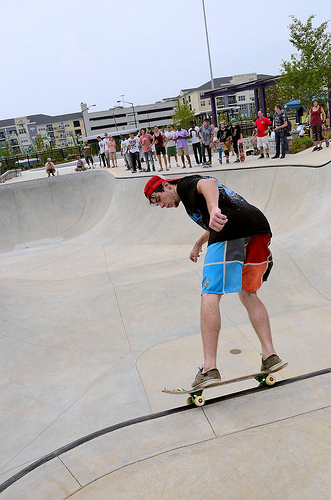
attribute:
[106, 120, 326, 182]
people — watching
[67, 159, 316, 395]
man — skateboarding, balancing, squatting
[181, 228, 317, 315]
shorts — multicolored, colors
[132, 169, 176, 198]
cap — red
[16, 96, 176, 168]
building — here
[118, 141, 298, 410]
skateboarder — tricking, watching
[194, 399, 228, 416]
wheel — white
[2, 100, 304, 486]
park — cement, here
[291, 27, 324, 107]
tree — green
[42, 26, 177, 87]
sky — clear, blue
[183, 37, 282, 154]
apartment — tall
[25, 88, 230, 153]
parking structure — multi-leveled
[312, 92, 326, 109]
helmet — worn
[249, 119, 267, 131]
shirt — red, black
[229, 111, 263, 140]
fence — black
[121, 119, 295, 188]
group — watching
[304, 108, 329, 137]
shirt — lavender, worn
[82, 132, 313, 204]
spectators — watching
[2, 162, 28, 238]
equipment — cement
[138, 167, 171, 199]
hat — worn, red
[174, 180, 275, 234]
shirt — black